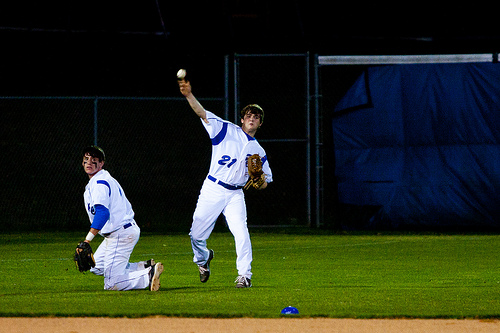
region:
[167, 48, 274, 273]
man is catching baseball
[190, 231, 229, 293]
man's foot is off ground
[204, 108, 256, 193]
man's shirt is white and blue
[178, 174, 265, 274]
man's pants are white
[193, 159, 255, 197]
man's belt is blue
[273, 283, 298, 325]
a helmet is on ground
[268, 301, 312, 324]
the helmet is blue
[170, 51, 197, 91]
the baseball is white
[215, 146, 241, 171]
blue numbers on man's shirt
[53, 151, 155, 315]
man is on knees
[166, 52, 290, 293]
baseball player throwing a baseball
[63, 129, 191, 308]
baseball player kneeling on the ground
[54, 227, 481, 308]
grass in a baseball outfield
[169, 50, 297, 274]
boy wearing a blue and white baseball uniform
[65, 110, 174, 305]
boy wearing a blue and white baseball uniform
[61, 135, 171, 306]
boy wearing a black baseball glove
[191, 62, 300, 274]
blue and white baseball jersey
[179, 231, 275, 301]
black baseball cleats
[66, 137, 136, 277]
boy wearing a white wristband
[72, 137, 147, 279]
boy wearing a long sleeved blue shirt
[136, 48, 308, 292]
baseball player in a uniform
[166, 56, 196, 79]
white baseball in the air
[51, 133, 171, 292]
baseball player kneeling on the ground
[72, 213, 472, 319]
light green grassy field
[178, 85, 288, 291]
white and blue uniform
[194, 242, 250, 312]
black and white sneakers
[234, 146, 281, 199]
dark brown baseball mit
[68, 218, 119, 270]
white wrist band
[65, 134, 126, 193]
boy with dark hair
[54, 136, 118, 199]
boy with a painted face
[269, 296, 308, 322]
a blue helmet on the grass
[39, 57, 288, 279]
boys playing baseball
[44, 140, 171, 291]
boy on his knees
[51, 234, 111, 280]
the boys glove is black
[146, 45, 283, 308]
the player is throwing the ball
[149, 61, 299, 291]
the uniform is white and blue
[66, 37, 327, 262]
a silver gate behind the boys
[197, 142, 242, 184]
the number 21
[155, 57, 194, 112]
the ball is white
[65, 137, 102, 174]
boy has black marks on his face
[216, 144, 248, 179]
21 on the jersey.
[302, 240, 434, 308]
The grass is green.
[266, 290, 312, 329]
Blue ball on the ground.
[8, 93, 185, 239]
Fence in the background.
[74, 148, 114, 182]
Black paint on the man's face.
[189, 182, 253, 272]
The pants are white.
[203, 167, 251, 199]
The belt is blue.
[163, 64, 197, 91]
The ball is white.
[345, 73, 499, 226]
Tarp on the fence.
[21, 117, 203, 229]
Bushes outside the fence.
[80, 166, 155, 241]
white baseball shirt with blue trim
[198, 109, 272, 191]
white baseball shirt with blue trim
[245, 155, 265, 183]
brown baseball catcher's mitt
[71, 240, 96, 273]
brown baseball catcher's mitt